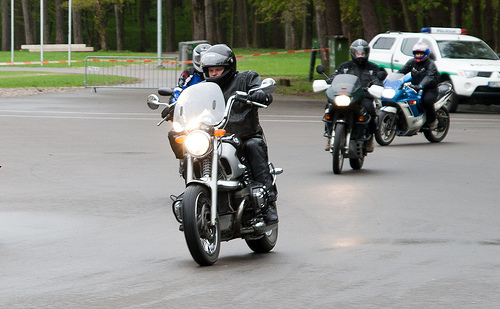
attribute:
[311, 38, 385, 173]
rider — third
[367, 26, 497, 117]
car — white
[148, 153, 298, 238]
motorcyle — silver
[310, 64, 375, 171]
motorcycle — black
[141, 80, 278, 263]
motorcycle — silver, black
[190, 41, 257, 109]
helmet — shiny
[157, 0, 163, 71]
pole — four, utility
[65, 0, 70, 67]
pole — utility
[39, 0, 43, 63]
pole — utility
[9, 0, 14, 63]
pole — utility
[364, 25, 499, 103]
police car — white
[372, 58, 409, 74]
stripe — green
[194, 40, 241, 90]
helmet — black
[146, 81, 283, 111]
mirrors — attached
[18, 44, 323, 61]
caution tape — yellow, orange, long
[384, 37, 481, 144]
rider — last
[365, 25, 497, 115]
suv — white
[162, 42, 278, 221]
man — riding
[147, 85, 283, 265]
motorcycle — first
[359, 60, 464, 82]
stripe — green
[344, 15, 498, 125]
suv — white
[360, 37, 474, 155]
motorcycle — blue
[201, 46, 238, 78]
helmet — black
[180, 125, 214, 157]
headlight — on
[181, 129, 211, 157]
headlight — lit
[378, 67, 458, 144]
motorbike — blue, silver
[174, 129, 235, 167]
headlight — lit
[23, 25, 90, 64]
bleachers — wooden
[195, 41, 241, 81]
helmet — black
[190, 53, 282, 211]
man — leading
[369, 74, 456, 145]
motorcycle — blue and silver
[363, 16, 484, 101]
vehicle — white and green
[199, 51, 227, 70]
visor — up